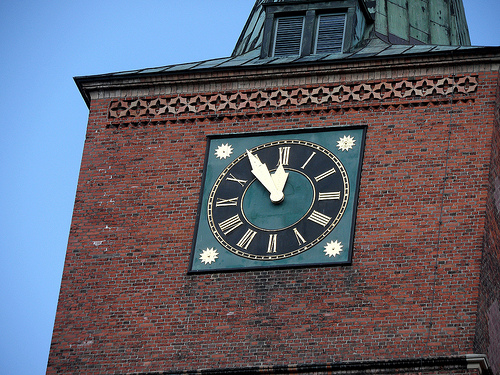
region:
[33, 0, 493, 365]
a brick clock tower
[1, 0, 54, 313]
a clear blue sky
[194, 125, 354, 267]
a clock on a tower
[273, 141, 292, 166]
the 12 on a Roman Numeral clock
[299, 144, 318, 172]
the 1 on a Roman Numeral clock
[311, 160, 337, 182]
the 2 on a Roman Numeral clock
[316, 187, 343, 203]
the 3 on a Roman Numeral clock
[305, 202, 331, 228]
the 4 on a Roman Numeral clock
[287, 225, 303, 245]
the 5 on a Roman Numeral clock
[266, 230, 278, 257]
the 6 on a Roman Numeral clock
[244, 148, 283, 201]
Long white hand on a clock.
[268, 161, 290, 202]
Small white hand of a clock.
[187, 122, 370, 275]
A black framed clock face on a green background.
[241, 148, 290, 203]
White hands of a clock.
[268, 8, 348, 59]
Small windows with slats across them above the clock.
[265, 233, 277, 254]
VI upside down on a clock face.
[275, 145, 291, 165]
XII on the top of a clock face.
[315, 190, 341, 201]
III in roman numerals on a clock face that represents 3.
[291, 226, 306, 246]
The roman numeral V on a clock face.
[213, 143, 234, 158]
The top white flower looking decoration to the left of a clock.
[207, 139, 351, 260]
the clock on the brick tower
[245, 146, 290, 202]
the hands on the clock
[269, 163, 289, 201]
the hour hand on the clock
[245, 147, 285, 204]
the minutes hand on the clock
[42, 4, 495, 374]
the brick tower with a clock on it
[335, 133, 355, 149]
the shape near the clock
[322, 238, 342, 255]
the shape near the clock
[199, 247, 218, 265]
the shape near the clock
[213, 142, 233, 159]
the shape near the clock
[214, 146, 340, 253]
the roman numerals on the face of the clock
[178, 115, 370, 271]
the clock is on the side of the building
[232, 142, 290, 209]
the clock has hands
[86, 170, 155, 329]
the building is made of brick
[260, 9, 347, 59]
the shutters are closed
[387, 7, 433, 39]
the roof is green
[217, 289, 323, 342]
the building is red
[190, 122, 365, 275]
the clock is blue and black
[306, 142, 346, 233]
the numbers are roman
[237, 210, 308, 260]
the numbers are silver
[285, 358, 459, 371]
the ledge is thin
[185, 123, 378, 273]
The clock on the building.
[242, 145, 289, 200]
The hands of the clock.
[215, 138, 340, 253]
The Roman numerals of the clock.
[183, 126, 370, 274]
The black border around the clock.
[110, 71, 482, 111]
The design above the clock.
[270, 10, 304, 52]
The shutters on the left side of the roof.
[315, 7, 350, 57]
The shutters on the right side of the roof.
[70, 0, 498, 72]
The green roof of the building.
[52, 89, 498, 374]
The bricks on the building.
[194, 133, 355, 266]
The sun shape designs in the corners of the clock.